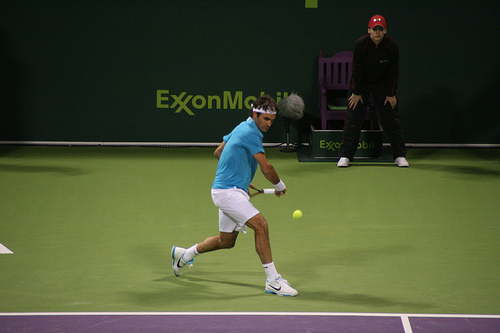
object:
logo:
[156, 89, 290, 117]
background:
[0, 2, 499, 153]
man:
[337, 11, 412, 169]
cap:
[368, 15, 387, 30]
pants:
[340, 84, 407, 156]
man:
[170, 94, 302, 302]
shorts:
[211, 185, 263, 233]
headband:
[250, 103, 276, 114]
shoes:
[167, 244, 193, 281]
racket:
[249, 183, 284, 199]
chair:
[317, 48, 375, 129]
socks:
[259, 261, 280, 282]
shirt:
[211, 117, 267, 194]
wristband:
[273, 179, 285, 192]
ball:
[292, 209, 302, 219]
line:
[1, 309, 500, 320]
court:
[0, 139, 499, 333]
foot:
[263, 275, 300, 298]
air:
[0, 0, 499, 333]